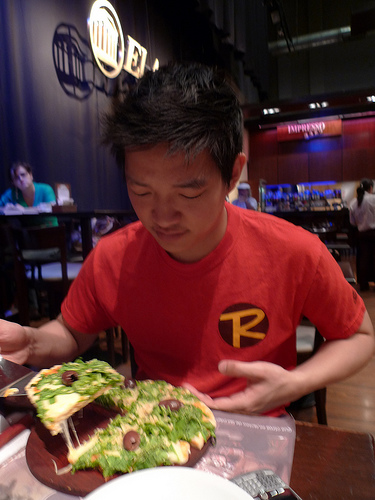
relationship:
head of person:
[88, 83, 290, 287] [56, 54, 285, 440]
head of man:
[88, 83, 290, 287] [62, 28, 343, 494]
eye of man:
[103, 172, 180, 222] [62, 28, 343, 494]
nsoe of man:
[126, 196, 210, 261] [62, 28, 343, 494]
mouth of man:
[140, 221, 205, 258] [62, 28, 343, 494]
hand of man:
[7, 258, 108, 378] [62, 28, 343, 494]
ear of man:
[168, 144, 286, 223] [62, 28, 343, 494]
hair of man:
[103, 43, 242, 134] [62, 28, 343, 494]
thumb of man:
[201, 326, 278, 378] [62, 28, 343, 494]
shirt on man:
[117, 223, 302, 412] [62, 28, 343, 494]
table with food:
[283, 442, 350, 492] [38, 359, 97, 424]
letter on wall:
[100, 21, 154, 62] [34, 63, 100, 181]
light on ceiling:
[267, 21, 340, 83] [256, 52, 310, 144]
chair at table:
[7, 212, 99, 315] [283, 442, 350, 492]